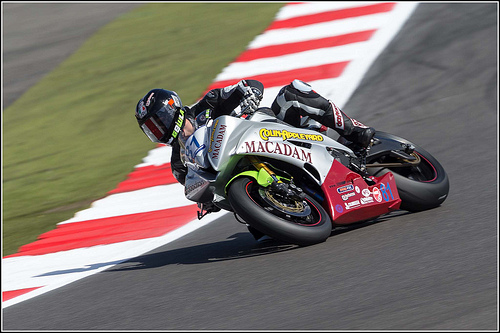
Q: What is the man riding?
A: A motorcycle.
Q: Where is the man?
A: On track.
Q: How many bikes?
A: One.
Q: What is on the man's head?
A: Helmet.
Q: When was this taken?
A: During the day.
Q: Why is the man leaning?
A: He is turning.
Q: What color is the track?
A: Black.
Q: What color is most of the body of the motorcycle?
A: Silver.